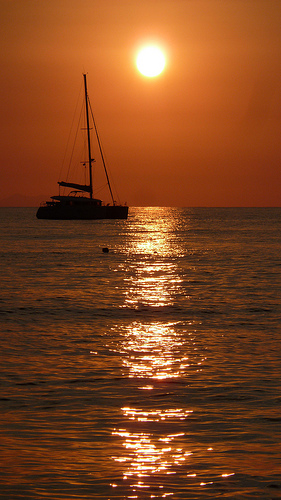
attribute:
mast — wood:
[82, 71, 96, 199]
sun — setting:
[129, 39, 169, 80]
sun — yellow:
[125, 36, 186, 87]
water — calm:
[32, 253, 238, 481]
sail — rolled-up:
[58, 181, 92, 191]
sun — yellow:
[128, 11, 188, 86]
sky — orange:
[2, 0, 279, 204]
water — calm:
[164, 231, 196, 251]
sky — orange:
[163, 59, 275, 156]